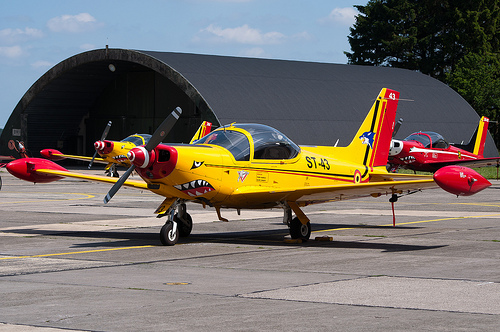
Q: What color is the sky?
A: Blue.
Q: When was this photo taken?
A: Daytime.